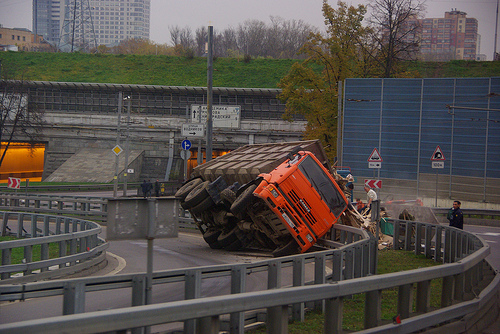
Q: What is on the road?
A: A truck.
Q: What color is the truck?
A: Orange.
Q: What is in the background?
A: Buildings.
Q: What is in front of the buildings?
A: A grassy hill.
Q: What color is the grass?
A: Green.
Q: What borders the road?
A: Fencing.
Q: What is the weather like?
A: Cloudy.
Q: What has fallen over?
A: Truck.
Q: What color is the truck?
A: Orange and brown.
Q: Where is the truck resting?
A: On it's side.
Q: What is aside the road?
A: Guard rails.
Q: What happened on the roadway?
A: Accident.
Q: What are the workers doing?
A: Cleaning up the accident.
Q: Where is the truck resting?
A: On its side.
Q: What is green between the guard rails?
A: Grass.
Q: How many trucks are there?
A: 1.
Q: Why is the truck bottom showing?
A: Tipped over.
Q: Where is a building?
A: Horizon.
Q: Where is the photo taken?
A: Outside by a highway.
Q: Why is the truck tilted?
A: It lost balance turning a corner.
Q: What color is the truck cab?
A: Orange.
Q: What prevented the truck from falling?
A: A guardrail.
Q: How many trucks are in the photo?
A: One.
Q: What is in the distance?
A: Buildings.